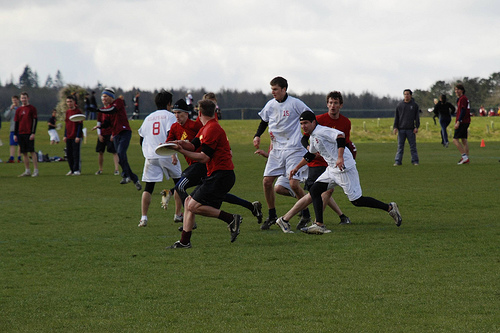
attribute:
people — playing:
[138, 75, 404, 250]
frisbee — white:
[157, 142, 180, 156]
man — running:
[288, 111, 403, 231]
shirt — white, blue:
[258, 97, 317, 149]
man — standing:
[394, 90, 422, 165]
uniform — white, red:
[137, 109, 185, 181]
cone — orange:
[480, 137, 486, 146]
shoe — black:
[228, 212, 242, 243]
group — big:
[3, 77, 403, 251]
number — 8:
[150, 123, 161, 135]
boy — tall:
[253, 78, 314, 230]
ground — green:
[1, 119, 499, 332]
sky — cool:
[0, 3, 499, 101]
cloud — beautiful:
[1, 2, 498, 100]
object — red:
[479, 135, 488, 146]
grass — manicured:
[2, 113, 498, 332]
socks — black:
[353, 197, 392, 213]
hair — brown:
[271, 76, 288, 88]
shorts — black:
[192, 171, 235, 209]